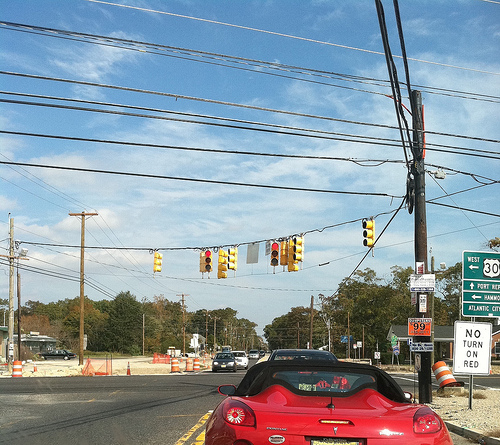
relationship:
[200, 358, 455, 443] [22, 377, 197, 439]
car on road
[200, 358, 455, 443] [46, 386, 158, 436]
car on street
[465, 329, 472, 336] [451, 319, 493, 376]
black letter on sign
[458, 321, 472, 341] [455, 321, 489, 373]
letter on sign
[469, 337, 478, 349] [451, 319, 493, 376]
letter on sign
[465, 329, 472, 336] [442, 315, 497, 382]
black letter on sign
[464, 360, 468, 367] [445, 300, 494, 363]
black letter on sign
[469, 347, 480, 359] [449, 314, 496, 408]
letter on sign